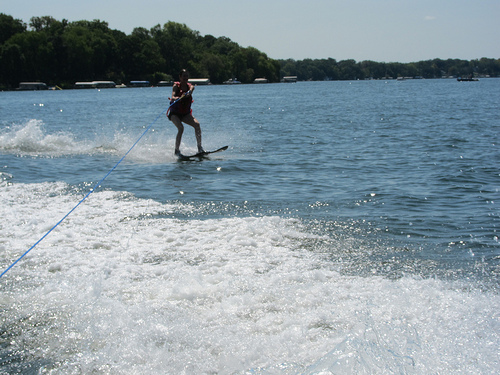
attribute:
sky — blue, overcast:
[0, 1, 498, 65]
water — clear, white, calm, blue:
[0, 78, 498, 374]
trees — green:
[1, 11, 285, 88]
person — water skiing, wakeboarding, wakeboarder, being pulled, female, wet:
[165, 69, 210, 157]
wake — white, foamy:
[0, 180, 500, 374]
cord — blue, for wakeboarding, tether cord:
[0, 97, 177, 281]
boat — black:
[454, 75, 478, 83]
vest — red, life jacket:
[173, 81, 193, 113]